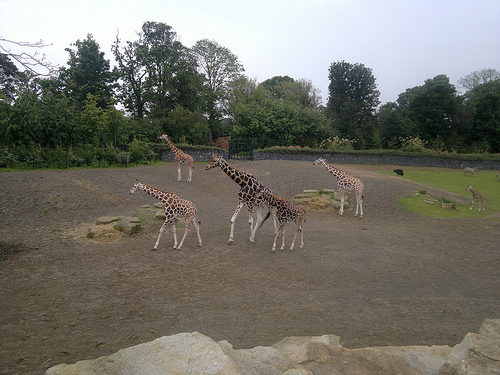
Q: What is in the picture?
A: Giraffes.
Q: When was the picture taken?
A: Day time.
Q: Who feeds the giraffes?
A: Zoo keeper.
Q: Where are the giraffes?
A: In a field.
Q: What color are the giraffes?
A: Brown.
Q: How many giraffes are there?
A: Six.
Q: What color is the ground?
A: Brown.